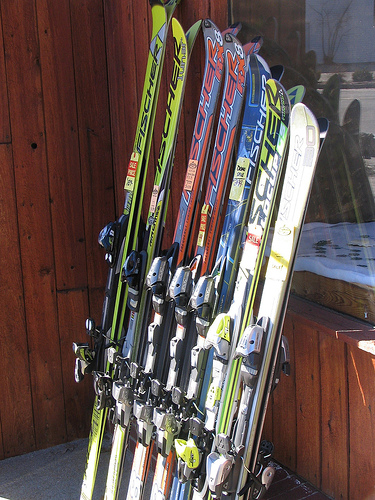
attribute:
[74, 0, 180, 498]
skis — red, blue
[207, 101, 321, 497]
ski — tall, thin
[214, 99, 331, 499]
ski — shining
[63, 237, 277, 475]
bindings — for boots, lined up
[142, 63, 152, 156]
writing — black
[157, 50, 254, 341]
skis — blue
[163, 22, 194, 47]
yellow — bright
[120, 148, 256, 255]
tags — yellow, red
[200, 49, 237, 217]
fischer — red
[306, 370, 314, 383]
spot — small, brown, wood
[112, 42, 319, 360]
skis — numerous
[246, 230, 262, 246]
stripe — red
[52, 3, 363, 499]
skis — leaning up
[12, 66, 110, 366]
wall — paneled, brown, wood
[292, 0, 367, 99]
window — wooden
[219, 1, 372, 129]
store window — recessed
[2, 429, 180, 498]
dusting — white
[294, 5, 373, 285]
exterior view — winter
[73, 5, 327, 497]
skis — displayed, leaning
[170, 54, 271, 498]
ski — blue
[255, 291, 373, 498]
wood — cherry red